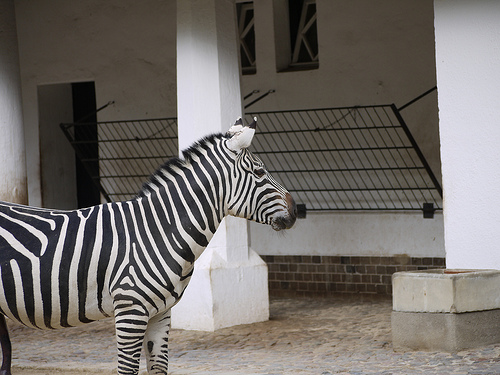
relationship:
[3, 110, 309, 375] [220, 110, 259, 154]
zebra has white ears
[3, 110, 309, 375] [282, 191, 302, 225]
zebra has brown nose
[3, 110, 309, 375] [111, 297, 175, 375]
zebra has striped legs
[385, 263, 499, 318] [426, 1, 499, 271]
blocks near column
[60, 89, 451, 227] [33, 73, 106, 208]
cage near door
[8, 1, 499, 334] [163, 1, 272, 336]
building has post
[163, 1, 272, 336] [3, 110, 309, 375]
post behind zebra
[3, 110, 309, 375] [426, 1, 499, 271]
zebra facing right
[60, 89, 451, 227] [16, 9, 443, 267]
grate on wall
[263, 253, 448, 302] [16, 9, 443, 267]
bricks on bottom of wall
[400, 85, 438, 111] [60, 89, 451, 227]
pole holding grate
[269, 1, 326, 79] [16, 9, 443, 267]
window in wall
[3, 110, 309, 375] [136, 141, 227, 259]
zebra has neck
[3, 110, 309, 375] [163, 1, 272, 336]
zebra on front a post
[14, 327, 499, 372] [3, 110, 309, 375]
ground under zebra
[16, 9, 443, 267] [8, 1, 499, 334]
wall color white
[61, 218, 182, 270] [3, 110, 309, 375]
stripes on zebra